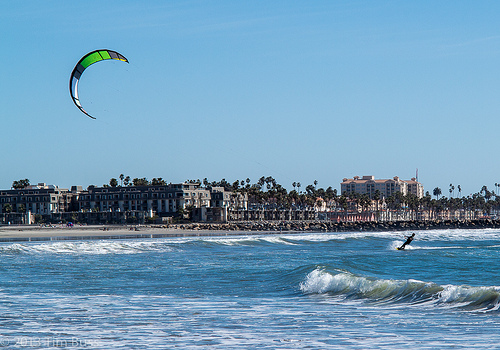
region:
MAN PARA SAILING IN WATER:
[349, 218, 474, 270]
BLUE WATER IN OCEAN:
[98, 262, 223, 290]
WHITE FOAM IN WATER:
[56, 237, 208, 313]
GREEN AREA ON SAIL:
[50, 41, 164, 115]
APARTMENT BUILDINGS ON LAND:
[17, 165, 234, 214]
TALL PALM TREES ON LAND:
[254, 164, 331, 199]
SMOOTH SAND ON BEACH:
[29, 233, 162, 253]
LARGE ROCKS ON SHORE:
[204, 210, 489, 231]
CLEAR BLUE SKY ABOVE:
[218, 32, 428, 150]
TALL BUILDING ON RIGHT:
[337, 140, 474, 240]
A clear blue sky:
[252, 75, 263, 88]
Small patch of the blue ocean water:
[156, 274, 174, 289]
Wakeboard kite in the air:
[68, 47, 132, 120]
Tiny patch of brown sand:
[85, 232, 93, 237]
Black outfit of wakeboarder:
[405, 238, 410, 243]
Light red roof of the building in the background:
[355, 178, 362, 183]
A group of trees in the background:
[119, 175, 145, 187]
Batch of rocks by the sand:
[354, 221, 374, 230]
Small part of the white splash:
[65, 245, 79, 253]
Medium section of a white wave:
[313, 274, 348, 290]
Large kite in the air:
[48, 26, 140, 129]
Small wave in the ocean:
[273, 249, 469, 329]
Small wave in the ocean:
[3, 232, 60, 265]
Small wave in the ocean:
[62, 221, 137, 266]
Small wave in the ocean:
[145, 233, 245, 260]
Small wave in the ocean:
[243, 221, 348, 249]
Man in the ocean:
[388, 231, 433, 258]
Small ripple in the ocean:
[225, 327, 271, 349]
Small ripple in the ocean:
[35, 300, 84, 326]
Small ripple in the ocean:
[170, 259, 222, 294]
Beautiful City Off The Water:
[1, 170, 498, 229]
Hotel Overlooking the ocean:
[338, 175, 425, 205]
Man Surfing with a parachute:
[58, 45, 418, 252]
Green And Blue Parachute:
[68, 50, 130, 120]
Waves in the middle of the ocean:
[276, 263, 498, 321]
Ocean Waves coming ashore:
[2, 224, 498, 258]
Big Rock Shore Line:
[156, 220, 498, 232]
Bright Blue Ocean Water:
[0, 233, 497, 348]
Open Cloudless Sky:
[0, 0, 497, 188]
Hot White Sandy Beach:
[0, 223, 217, 236]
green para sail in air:
[57, 38, 124, 115]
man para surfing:
[395, 226, 416, 266]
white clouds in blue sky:
[174, 31, 231, 82]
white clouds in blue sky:
[265, 21, 326, 99]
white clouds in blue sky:
[312, 18, 374, 95]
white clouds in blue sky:
[404, 18, 465, 76]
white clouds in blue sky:
[387, 106, 452, 157]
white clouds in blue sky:
[252, 109, 299, 153]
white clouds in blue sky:
[311, 91, 366, 139]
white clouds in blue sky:
[134, 98, 185, 130]